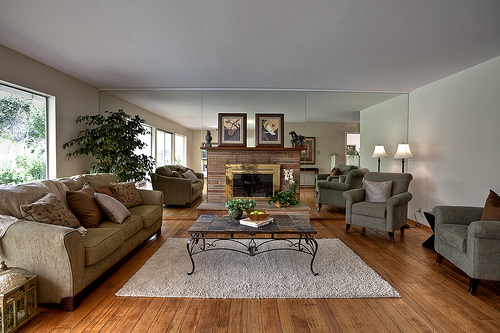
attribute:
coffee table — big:
[185, 198, 327, 276]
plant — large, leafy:
[63, 108, 154, 183]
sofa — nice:
[1, 159, 180, 304]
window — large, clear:
[11, 93, 153, 238]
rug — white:
[151, 247, 445, 294]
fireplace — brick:
[206, 146, 299, 210]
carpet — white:
[211, 253, 315, 307]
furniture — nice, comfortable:
[13, 123, 497, 330]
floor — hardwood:
[18, 191, 499, 331]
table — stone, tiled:
[174, 197, 331, 284]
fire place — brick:
[189, 121, 334, 225]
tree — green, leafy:
[62, 101, 159, 182]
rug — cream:
[140, 216, 417, 321]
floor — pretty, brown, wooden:
[21, 217, 498, 331]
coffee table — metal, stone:
[182, 208, 319, 277]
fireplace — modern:
[199, 143, 306, 219]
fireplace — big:
[201, 149, 302, 204]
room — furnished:
[0, 1, 497, 331]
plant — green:
[224, 195, 256, 225]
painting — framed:
[214, 108, 245, 145]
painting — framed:
[255, 113, 285, 152]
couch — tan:
[2, 173, 162, 308]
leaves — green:
[275, 186, 302, 199]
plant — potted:
[274, 187, 304, 211]